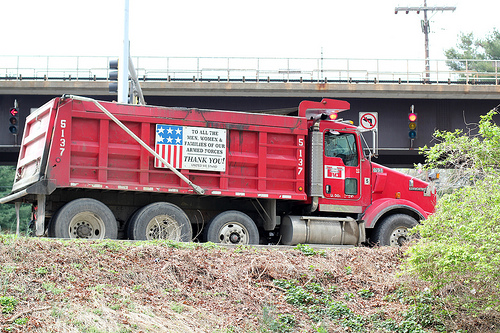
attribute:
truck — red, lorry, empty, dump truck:
[1, 90, 447, 247]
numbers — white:
[292, 137, 308, 180]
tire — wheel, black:
[50, 197, 122, 245]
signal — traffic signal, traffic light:
[404, 112, 420, 143]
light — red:
[405, 111, 418, 122]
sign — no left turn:
[355, 110, 380, 133]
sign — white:
[148, 122, 232, 174]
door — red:
[320, 126, 366, 202]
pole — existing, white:
[116, 1, 134, 104]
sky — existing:
[1, 2, 499, 81]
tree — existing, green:
[436, 24, 499, 82]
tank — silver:
[276, 213, 363, 248]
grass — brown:
[1, 241, 419, 332]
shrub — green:
[400, 103, 499, 331]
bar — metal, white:
[61, 91, 209, 197]